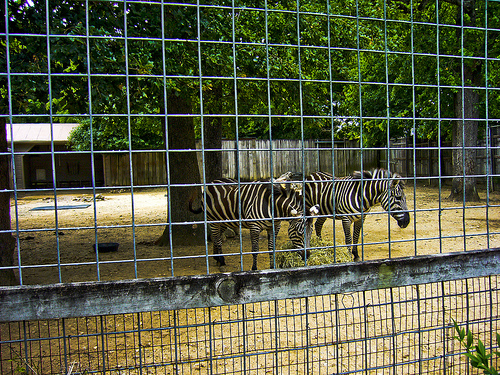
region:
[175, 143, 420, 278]
zebras standing besides each other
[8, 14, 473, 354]
fence enclosing the area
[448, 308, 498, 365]
green leaves on branch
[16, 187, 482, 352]
ground where zebras stand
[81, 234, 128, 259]
container on ground near tree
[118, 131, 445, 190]
wooden fence behind zebras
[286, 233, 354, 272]
ball of grass for feeding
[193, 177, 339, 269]
zebra feeding on the grass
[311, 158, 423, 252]
zebra not feeding on grass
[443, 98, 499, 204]
trunk of a tree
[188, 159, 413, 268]
Two zebra are standing behind the fence.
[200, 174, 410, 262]
zebra are black and white color.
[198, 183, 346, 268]
Zebra is eating grass.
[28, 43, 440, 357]
Fence is blue and black color.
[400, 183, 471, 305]
Ground is brown color.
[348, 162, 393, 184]
Zebra has short hairs on back.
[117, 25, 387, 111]
Leaves are green color.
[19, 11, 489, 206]
Trees are behind the zebra.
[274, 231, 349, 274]
Grass is green and brown color.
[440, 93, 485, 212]
Woods are grey color.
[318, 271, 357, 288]
the board is weathered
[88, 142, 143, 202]
the gate is gray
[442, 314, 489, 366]
the plant is outside the fence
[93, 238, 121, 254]
the bowl is on the ground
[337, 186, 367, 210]
the zebra has black stripes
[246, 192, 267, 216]
the zebra has white stripes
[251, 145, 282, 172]
the fence is weathered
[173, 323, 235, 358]
the fence is gray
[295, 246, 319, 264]
the zebra is eating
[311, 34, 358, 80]
the leaves are green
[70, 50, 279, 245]
the fence is blue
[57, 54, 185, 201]
the fence is blue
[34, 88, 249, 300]
the fence is blue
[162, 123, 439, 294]
two zebras inside the fence